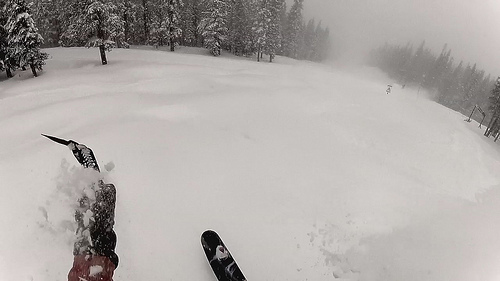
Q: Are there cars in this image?
A: No, there are no cars.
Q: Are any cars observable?
A: No, there are no cars.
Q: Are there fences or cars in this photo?
A: No, there are no cars or fences.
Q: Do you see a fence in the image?
A: No, there are no fences.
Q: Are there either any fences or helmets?
A: No, there are no fences or helmets.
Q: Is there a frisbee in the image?
A: No, there are no frisbees.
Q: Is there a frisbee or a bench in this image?
A: No, there are no frisbees or benches.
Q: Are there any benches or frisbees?
A: No, there are no frisbees or benches.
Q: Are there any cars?
A: No, there are no cars.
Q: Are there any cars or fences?
A: No, there are no cars or fences.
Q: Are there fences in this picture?
A: No, there are no fences.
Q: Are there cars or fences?
A: No, there are no fences or cars.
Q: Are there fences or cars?
A: No, there are no fences or cars.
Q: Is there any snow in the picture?
A: Yes, there is snow.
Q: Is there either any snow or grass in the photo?
A: Yes, there is snow.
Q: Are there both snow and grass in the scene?
A: No, there is snow but no grass.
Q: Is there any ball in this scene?
A: No, there are no balls.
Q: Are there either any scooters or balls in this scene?
A: No, there are no balls or scooters.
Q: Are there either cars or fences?
A: No, there are no cars or fences.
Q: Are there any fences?
A: No, there are no fences.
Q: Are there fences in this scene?
A: No, there are no fences.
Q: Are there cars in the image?
A: No, there are no cars.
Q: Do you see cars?
A: No, there are no cars.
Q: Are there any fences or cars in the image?
A: No, there are no cars or fences.